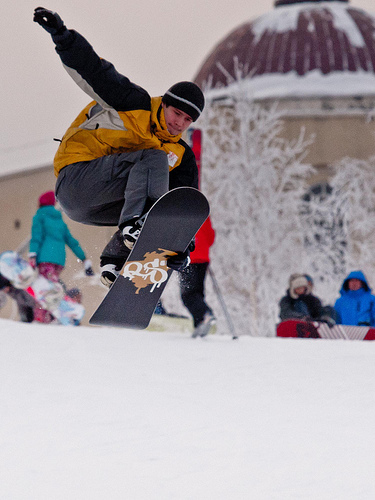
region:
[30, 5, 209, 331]
man on black snowboard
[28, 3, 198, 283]
man wearing yellow and black jacket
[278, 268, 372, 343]
people in jackets holding snowboard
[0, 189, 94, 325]
woman in blue jacket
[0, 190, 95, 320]
woman carrying multicolored snowboard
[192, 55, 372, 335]
trees covered in snow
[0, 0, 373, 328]
red dome over tan building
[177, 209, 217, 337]
person in red jacket and black pants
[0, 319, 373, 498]
snow on ground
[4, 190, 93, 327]
woman wearing pink hat and pants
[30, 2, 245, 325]
Person on a snowboard.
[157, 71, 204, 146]
Black hat with a white stripe.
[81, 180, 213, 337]
Black snowboard with a symbol.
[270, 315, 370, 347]
Red snowboard with white stripes.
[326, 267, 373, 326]
Person wearing a blue jacket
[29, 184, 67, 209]
Person wearing a pink hat.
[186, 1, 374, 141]
Building with a dome roof.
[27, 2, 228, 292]
Person wearing a yellow jacket.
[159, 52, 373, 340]
Tree covered in snow.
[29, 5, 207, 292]
Person wearing gray pants.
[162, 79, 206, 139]
black and white cap on man's head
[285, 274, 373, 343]
two people holding surfboard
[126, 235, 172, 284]
logo design on black surfboard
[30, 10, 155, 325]
boy in gold and black jacket on snow board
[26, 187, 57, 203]
lady wearing dark pink cap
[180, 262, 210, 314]
someone who is wearing black pants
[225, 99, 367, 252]
a portion of snow covered branches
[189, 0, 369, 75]
rounded dome on top of beige building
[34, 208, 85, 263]
lady wearing blue long-sleeved jacket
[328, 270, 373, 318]
person wearing hooded blue jacket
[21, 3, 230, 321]
a man doing a jump on a snowboard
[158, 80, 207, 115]
a black knit cap on the man doing the jump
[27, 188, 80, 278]
a woman in a blue jacket walking away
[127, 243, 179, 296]
the design on the bottom of the man's snowboard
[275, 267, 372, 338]
two people with a snowboard in the background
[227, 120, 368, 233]
snow covered trees in the background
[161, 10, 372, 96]
a domed roof on a building behind the event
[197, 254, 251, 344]
a black ski pole someone is carrying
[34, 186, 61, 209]
a dark pink hat on a woman behind the jumper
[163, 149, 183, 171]
a tag on the jacket of the man doing the jump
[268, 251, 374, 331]
people watching a snowboarder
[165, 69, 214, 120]
a black snow cap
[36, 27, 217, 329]
a guy snowboarding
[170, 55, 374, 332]
snow covered trees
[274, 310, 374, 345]
a red snow board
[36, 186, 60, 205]
a fuschia ski cap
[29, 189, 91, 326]
a person in a green jacket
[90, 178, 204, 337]
a black snow board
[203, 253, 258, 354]
a ski pole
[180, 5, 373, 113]
the dome of a large building